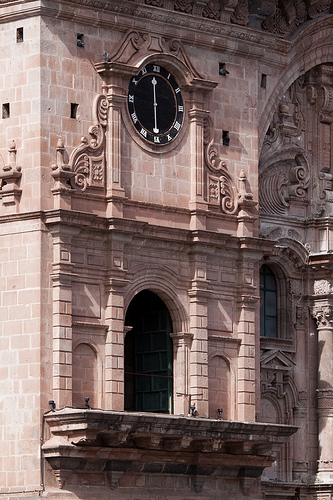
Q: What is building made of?
A: Brick.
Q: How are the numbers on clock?
A: White.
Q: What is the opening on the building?
A: Arch.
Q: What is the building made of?
A: Bricks.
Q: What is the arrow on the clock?
A: Hands.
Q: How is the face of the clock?
A: Black.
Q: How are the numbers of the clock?
A: Roman numerals.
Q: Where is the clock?
A: Building.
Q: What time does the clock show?
A: 6:00.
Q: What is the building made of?
A: Concrete.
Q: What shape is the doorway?
A: Arched.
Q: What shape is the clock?
A: Round.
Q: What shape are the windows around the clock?
A: Rectangle.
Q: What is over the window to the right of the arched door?
A: Bars.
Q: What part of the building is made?
A: Corner.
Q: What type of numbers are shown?
A: Roman numerals.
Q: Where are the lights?
A: Around the balcony.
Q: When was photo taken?
A: Daytime.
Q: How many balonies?
A: 1.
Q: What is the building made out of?
A: Brick.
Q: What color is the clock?
A: Black and white.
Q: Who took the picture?
A: A person.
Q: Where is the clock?
A: On building.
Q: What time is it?
A: 12;30.